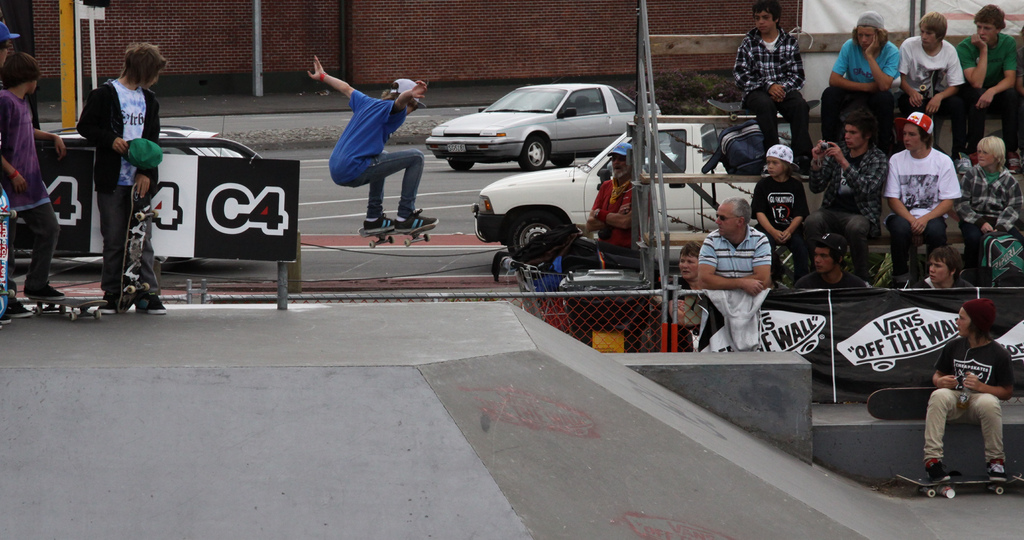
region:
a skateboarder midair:
[313, 57, 450, 254]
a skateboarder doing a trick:
[305, 57, 441, 253]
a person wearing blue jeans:
[349, 145, 429, 219]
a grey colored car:
[430, 76, 646, 163]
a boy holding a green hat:
[81, 48, 164, 172]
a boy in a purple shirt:
[2, 50, 60, 193]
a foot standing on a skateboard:
[16, 265, 105, 317]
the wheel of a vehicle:
[506, 208, 560, 246]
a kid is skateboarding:
[311, 62, 439, 246]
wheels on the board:
[365, 238, 426, 246]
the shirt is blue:
[330, 93, 406, 171]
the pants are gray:
[348, 142, 421, 219]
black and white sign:
[39, 159, 297, 258]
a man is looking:
[694, 197, 768, 293]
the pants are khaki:
[924, 387, 1002, 471]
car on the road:
[435, 78, 635, 168]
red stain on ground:
[473, 372, 595, 439]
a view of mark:
[414, 325, 620, 494]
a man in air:
[302, 56, 560, 328]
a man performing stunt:
[259, 56, 522, 298]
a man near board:
[73, 64, 232, 400]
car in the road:
[405, 56, 747, 202]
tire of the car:
[473, 110, 582, 197]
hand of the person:
[397, 67, 477, 140]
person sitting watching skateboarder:
[920, 296, 1006, 486]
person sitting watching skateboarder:
[917, 245, 971, 290]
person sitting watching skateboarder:
[784, 224, 864, 282]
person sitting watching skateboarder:
[696, 194, 770, 297]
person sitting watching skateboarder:
[671, 245, 698, 288]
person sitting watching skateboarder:
[804, 112, 881, 253]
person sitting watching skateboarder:
[880, 102, 960, 270]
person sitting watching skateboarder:
[954, 132, 1016, 260]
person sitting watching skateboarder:
[730, 4, 817, 170]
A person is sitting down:
[818, 115, 872, 242]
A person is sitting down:
[882, 96, 958, 236]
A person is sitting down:
[951, 5, 1022, 120]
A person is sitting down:
[898, 7, 949, 131]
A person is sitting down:
[824, 10, 913, 150]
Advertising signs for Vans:
[702, 295, 1022, 378]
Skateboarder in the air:
[302, 55, 443, 245]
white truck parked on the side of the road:
[469, 124, 777, 260]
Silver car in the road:
[428, 83, 659, 166]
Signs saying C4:
[7, 137, 293, 256]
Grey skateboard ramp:
[11, 298, 1018, 537]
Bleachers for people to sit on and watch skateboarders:
[639, 2, 1022, 372]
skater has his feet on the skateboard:
[902, 394, 1020, 495]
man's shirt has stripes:
[687, 227, 775, 285]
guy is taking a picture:
[809, 118, 876, 171]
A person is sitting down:
[685, 179, 772, 347]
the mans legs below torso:
[93, 183, 163, 310]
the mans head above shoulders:
[118, 38, 173, 89]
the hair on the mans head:
[119, 31, 167, 67]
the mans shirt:
[323, 76, 403, 160]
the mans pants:
[95, 184, 166, 312]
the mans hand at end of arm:
[301, 50, 327, 85]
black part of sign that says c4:
[194, 165, 289, 252]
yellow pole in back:
[51, 1, 75, 120]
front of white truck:
[462, 169, 508, 243]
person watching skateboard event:
[737, 2, 815, 171]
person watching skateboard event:
[815, 13, 904, 163]